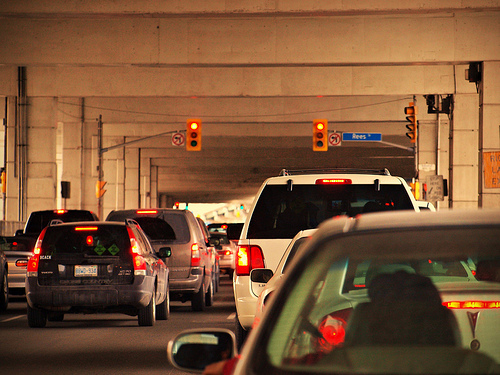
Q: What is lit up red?
A: Two traffic lights.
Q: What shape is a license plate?
A: Rectangular.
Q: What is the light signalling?
A: Stop.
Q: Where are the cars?
A: On street.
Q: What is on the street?
A: Cars.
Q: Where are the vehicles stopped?
A: Intersection.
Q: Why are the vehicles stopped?
A: Red light.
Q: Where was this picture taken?
A: Under a bridge.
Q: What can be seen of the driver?
A: Back of head.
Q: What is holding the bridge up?
A: Pillars.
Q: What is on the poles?
A: Traffic lights.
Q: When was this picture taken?
A: Rush Hour.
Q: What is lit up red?
A: Traffic lights.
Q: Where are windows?
A: On the vehicles.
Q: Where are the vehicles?
A: On the road.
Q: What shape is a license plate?
A: Rectangular.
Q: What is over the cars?
A: A tunnel.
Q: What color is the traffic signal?
A: Red.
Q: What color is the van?
A: White.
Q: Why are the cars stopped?
A: Red light.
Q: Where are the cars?
A: Tunnel.